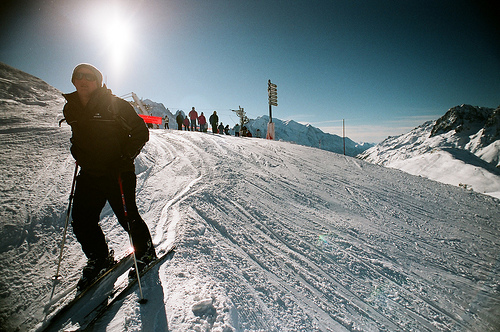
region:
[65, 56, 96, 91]
person has white cap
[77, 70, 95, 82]
man is wearing glasses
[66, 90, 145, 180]
man has black coat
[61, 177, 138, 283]
man has black pants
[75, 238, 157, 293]
man has black shoes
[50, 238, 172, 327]
black and yellow skis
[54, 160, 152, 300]
red and white ski poles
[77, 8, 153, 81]
sun is shining brightly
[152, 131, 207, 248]
white tracks in snow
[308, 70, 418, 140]
blue and white sky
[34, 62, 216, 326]
a man that is skiing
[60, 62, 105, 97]
the head of a man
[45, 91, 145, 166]
the coat of a man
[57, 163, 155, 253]
the pants of a man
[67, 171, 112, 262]
the right leg of a man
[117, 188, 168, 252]
the left leg of a man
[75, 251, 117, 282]
the right foot of a man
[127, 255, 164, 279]
the left foot of a man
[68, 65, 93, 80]
the goggles of a man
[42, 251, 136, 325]
the black skis of a man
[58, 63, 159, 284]
person wearing snow cloths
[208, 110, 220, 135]
person wearing snow cloths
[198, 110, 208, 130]
person wearing snow cloths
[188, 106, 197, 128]
person wearing snow cloths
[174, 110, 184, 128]
person wearing snow cloths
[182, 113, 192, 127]
person wearing snow cloths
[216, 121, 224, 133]
person wearing snow cloths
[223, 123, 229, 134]
person wearing snow cloths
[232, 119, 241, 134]
person wearing snow cloths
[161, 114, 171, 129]
person wearing snow cloths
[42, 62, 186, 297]
A person skating on snow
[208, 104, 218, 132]
A person skating on snow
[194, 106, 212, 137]
A person skating on snow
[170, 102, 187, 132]
A person skating on snow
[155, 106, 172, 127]
A person skating on snow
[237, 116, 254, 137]
A person skating on snow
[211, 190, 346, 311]
A white snow field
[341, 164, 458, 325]
A white snow field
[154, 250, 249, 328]
A white snow field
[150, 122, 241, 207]
A white snow field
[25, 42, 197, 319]
the man is skiing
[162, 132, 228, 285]
ski tracks on the snow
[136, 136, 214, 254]
ski tracks on the snow